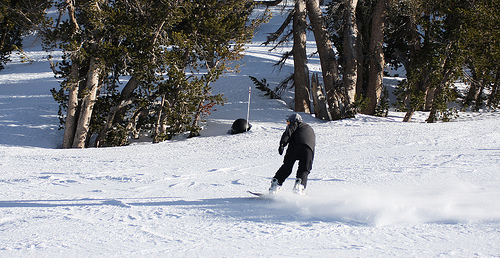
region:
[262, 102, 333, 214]
Man snowboarding.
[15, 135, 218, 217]
Ground covered in snow.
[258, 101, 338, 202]
Man wearing all black.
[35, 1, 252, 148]
Evergreen trees growing in the forest.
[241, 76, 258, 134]
White post standing in the snow.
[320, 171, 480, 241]
Cloud of snow caused by the snowboarder.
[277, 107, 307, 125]
Helmet on the snowboarders head for safety.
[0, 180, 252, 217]
Shadow on the snow from the snowboarder.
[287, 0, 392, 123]
Tall group of trees on the mountainside.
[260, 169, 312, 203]
White boots on the man's feet.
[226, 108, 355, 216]
Man snowboarding in the snow.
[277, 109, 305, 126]
Grey helmet on the man's head.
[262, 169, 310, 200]
White snow boots on the man's feet.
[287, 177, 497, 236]
White powder from the man snowboarding.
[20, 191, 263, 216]
Man's shadow on the ground.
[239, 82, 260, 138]
White metal pole standing in the snow.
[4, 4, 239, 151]
Shaded area of the woods.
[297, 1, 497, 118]
Evergreen trees filled with green leaves.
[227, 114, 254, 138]
Black object sticking out of the snow.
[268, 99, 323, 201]
man on snow board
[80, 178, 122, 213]
white snow on hill side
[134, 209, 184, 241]
white snow on hill side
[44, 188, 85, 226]
white snow on hill side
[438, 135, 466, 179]
white snow on hill side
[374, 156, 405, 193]
white snow on hill side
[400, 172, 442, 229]
white snow on hill side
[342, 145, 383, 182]
white snow on hill side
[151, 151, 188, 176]
white snow on hill side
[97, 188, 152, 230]
white snow on hill side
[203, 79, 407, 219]
a snowboarder coming down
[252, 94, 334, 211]
an all black outfit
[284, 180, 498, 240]
snow kicking up in air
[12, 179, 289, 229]
a shadow from snowboarder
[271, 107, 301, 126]
a helmet on his head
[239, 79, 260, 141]
a white pole sticking up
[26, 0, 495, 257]
snow covers the ground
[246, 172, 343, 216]
white boots on feet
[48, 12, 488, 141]
several trees sticking up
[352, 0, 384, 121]
a trunk of a tree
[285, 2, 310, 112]
a trunk of a tree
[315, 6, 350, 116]
a trunk of a tree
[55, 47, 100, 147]
a trunks of a trees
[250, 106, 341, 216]
a person in black skiing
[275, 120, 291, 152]
the arm of a person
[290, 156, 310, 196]
the leg of a person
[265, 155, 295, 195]
the leg of a person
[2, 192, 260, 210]
a shadow on the snow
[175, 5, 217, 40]
the leaves of a tree